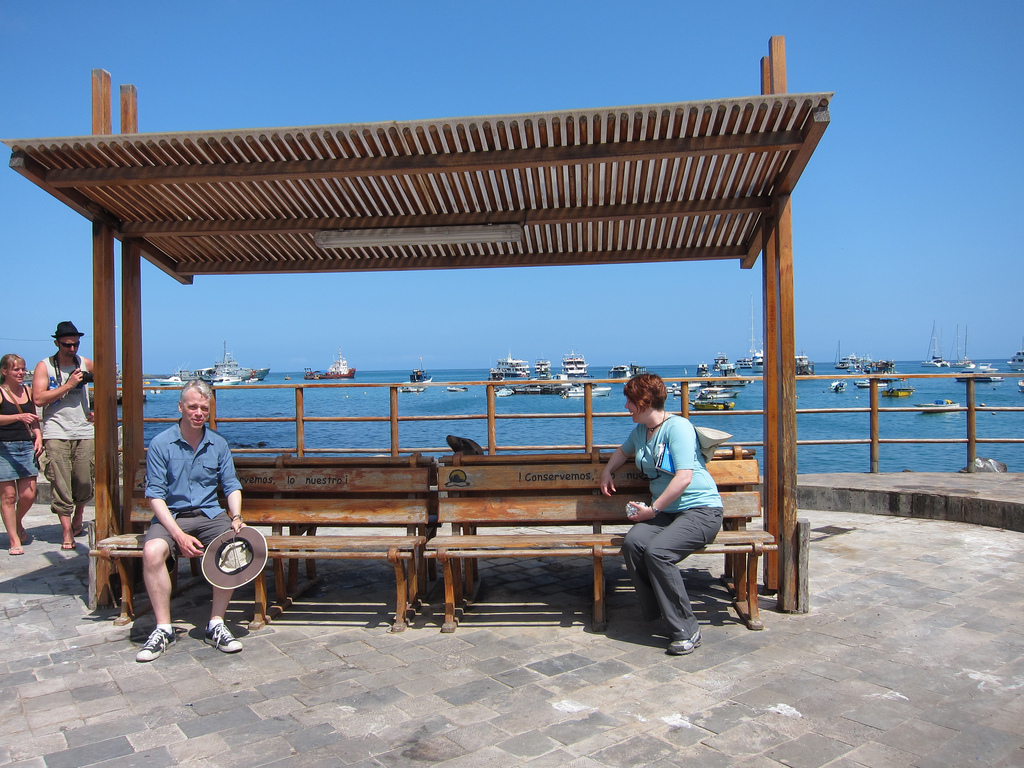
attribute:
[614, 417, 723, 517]
top — blue 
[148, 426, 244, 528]
shirt — blue 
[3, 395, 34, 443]
top — black 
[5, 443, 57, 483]
skirt — blue jean 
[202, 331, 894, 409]
boats — distance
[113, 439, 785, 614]
bench — back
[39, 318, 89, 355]
hat — black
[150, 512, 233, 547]
shorts — gray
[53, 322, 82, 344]
hat — black 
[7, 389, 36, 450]
top —  black tank 